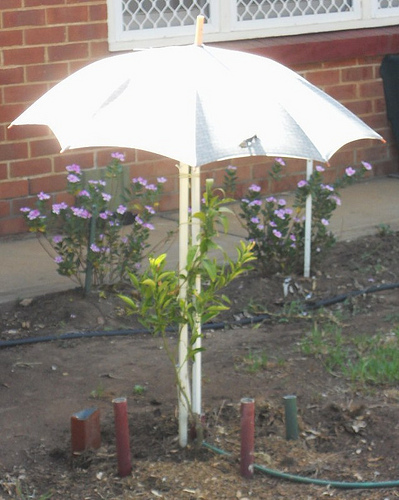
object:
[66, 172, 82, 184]
flowers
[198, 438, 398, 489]
hose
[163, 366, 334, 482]
garden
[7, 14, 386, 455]
umbrella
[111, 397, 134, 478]
pole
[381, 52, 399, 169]
pail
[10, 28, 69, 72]
wall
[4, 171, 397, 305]
sidewalk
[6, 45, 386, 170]
canopy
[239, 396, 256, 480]
post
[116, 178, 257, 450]
plant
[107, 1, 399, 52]
window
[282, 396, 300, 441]
pipe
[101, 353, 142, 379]
dirt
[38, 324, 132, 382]
ground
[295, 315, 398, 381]
grass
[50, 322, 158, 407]
shade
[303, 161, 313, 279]
stakes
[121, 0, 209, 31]
lattic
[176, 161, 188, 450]
poles